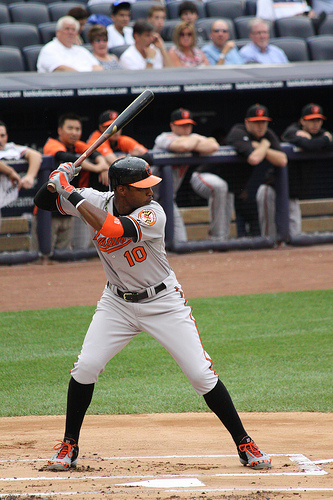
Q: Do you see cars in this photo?
A: No, there are no cars.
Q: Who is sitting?
A: The people are sitting.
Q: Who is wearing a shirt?
A: The people are wearing a shirt.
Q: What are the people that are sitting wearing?
A: The people are wearing a shirt.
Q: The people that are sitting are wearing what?
A: The people are wearing a shirt.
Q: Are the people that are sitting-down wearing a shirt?
A: Yes, the people are wearing a shirt.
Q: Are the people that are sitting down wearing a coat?
A: No, the people are wearing a shirt.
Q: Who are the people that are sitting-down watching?
A: The people are watching the man.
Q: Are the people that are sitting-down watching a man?
A: Yes, the people are watching a man.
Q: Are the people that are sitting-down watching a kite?
A: No, the people are watching a man.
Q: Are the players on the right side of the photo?
A: Yes, the players are on the right of the image.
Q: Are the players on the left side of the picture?
A: No, the players are on the right of the image.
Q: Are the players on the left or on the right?
A: The players are on the right of the image.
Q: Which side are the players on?
A: The players are on the right of the image.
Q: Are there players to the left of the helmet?
A: No, the players are to the right of the helmet.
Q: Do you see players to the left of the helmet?
A: No, the players are to the right of the helmet.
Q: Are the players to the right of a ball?
A: No, the players are to the right of the helmet.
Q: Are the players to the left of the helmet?
A: No, the players are to the right of the helmet.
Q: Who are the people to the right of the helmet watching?
A: The players are watching the man.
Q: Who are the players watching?
A: The players are watching the man.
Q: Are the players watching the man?
A: Yes, the players are watching the man.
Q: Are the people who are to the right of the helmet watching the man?
A: Yes, the players are watching the man.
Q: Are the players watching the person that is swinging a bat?
A: Yes, the players are watching the man.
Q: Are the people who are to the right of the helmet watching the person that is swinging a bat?
A: Yes, the players are watching the man.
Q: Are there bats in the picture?
A: Yes, there is a bat.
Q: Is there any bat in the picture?
A: Yes, there is a bat.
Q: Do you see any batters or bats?
A: Yes, there is a bat.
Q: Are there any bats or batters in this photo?
A: Yes, there is a bat.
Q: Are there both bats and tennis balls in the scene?
A: No, there is a bat but no tennis balls.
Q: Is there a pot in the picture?
A: No, there are no pots.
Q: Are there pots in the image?
A: No, there are no pots.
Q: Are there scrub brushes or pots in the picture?
A: No, there are no pots or scrub brushes.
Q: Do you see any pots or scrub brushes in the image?
A: No, there are no pots or scrub brushes.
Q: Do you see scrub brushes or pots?
A: No, there are no pots or scrub brushes.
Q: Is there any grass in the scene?
A: Yes, there is grass.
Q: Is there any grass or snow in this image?
A: Yes, there is grass.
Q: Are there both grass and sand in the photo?
A: No, there is grass but no sand.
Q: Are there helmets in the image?
A: Yes, there is a helmet.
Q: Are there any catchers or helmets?
A: Yes, there is a helmet.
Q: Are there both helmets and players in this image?
A: Yes, there are both a helmet and a player.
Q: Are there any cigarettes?
A: No, there are no cigarettes.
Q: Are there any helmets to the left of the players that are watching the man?
A: Yes, there is a helmet to the left of the players.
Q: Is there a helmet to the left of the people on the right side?
A: Yes, there is a helmet to the left of the players.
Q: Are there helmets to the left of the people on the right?
A: Yes, there is a helmet to the left of the players.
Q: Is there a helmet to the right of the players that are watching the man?
A: No, the helmet is to the left of the players.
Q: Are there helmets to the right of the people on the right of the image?
A: No, the helmet is to the left of the players.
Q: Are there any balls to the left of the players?
A: No, there is a helmet to the left of the players.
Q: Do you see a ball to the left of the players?
A: No, there is a helmet to the left of the players.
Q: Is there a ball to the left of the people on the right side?
A: No, there is a helmet to the left of the players.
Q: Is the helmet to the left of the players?
A: Yes, the helmet is to the left of the players.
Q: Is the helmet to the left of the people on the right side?
A: Yes, the helmet is to the left of the players.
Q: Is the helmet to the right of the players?
A: No, the helmet is to the left of the players.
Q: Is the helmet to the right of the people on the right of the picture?
A: No, the helmet is to the left of the players.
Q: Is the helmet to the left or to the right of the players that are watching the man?
A: The helmet is to the left of the players.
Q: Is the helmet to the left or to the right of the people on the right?
A: The helmet is to the left of the players.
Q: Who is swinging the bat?
A: The man is swinging the bat.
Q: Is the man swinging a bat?
A: Yes, the man is swinging a bat.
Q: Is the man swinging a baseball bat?
A: No, the man is swinging a bat.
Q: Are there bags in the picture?
A: No, there are no bags.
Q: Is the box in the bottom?
A: Yes, the box is in the bottom of the image.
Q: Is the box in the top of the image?
A: No, the box is in the bottom of the image.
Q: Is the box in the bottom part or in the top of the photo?
A: The box is in the bottom of the image.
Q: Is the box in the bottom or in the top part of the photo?
A: The box is in the bottom of the image.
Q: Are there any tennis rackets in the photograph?
A: No, there are no tennis rackets.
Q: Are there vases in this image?
A: No, there are no vases.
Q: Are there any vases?
A: No, there are no vases.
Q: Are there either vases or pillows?
A: No, there are no vases or pillows.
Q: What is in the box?
A: The home plate is in the box.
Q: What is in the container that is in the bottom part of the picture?
A: The home plate is in the box.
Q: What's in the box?
A: The home plate is in the box.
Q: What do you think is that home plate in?
A: The home plate is in the box.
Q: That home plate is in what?
A: The home plate is in the box.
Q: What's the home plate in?
A: The home plate is in the box.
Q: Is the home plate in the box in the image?
A: Yes, the home plate is in the box.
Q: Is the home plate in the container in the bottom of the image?
A: Yes, the home plate is in the box.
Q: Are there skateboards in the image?
A: No, there are no skateboards.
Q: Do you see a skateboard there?
A: No, there are no skateboards.